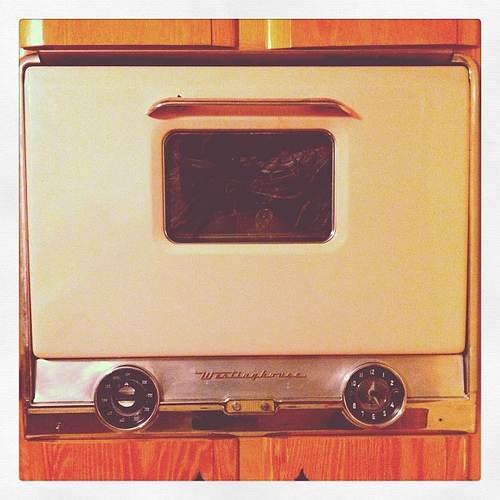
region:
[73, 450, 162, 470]
wood used for creation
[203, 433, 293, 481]
pieced of carved wood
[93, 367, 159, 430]
circular knob for tuning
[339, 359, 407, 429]
circular clock for time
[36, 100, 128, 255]
beige off white door-like structure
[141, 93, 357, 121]
handle for door-like structure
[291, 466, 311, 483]
black point on wood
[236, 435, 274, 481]
piece of wood protruding from larger piece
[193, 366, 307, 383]
name of brand engraved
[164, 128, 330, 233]
small window-like structure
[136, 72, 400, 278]
Window on the oven.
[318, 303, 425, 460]
Dial on the oven.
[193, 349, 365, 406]
Brand on the oven.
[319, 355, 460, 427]
Numbers on the dial.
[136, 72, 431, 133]
Handle on the oven.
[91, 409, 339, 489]
Wood cabinet under the oven.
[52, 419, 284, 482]
Cabinet under the oven.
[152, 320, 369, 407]
Silver part of the oven.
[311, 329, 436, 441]
Black dial on the oven.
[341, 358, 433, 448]
White numbers on the dial.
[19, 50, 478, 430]
the oven is an antique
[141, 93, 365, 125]
the handle is made of metal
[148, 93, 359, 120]
the handle is made of steel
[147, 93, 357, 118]
the handle is shiny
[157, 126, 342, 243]
a window is on the oven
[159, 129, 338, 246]
the window is made of glass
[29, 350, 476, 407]
the base is made of metal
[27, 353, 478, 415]
the base is made of steel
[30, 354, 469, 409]
the base is shiny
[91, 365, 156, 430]
a dial is on the stove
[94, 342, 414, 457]
Two black and silver knobs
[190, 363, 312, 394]
Logo in silver in front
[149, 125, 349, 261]
Small black window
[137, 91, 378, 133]
Small silver handle on stove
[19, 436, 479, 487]
Two brown cabinets under stove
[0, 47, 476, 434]
Silver and white stove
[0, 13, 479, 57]
Two brown cabinets above stove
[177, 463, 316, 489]
Top of two black handles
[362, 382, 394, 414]
Silver hands on knob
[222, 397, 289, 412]
Two silver bolts